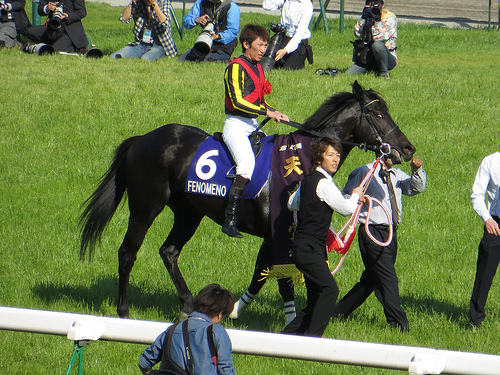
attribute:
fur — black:
[128, 124, 175, 181]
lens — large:
[369, 5, 381, 18]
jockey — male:
[218, 22, 285, 239]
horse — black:
[120, 93, 414, 313]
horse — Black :
[75, 80, 422, 322]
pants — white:
[210, 96, 288, 240]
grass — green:
[16, 83, 124, 339]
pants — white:
[220, 114, 263, 176]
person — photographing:
[346, 0, 403, 81]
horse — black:
[59, 43, 449, 332]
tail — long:
[78, 142, 123, 267]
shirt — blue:
[135, 308, 237, 373]